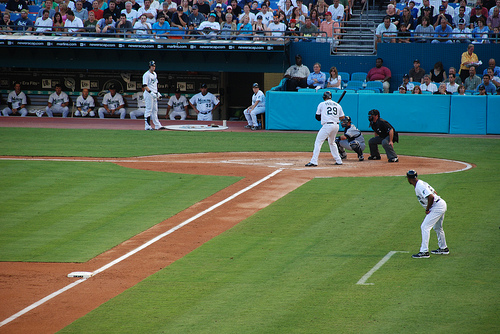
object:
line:
[0, 149, 229, 165]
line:
[358, 279, 376, 285]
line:
[390, 249, 410, 254]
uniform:
[414, 179, 448, 253]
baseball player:
[402, 168, 450, 259]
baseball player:
[140, 59, 167, 131]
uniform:
[141, 70, 166, 131]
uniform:
[242, 89, 265, 127]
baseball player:
[241, 82, 265, 131]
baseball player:
[188, 84, 221, 122]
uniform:
[187, 92, 220, 121]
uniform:
[167, 94, 187, 120]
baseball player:
[164, 85, 190, 120]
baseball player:
[96, 81, 128, 120]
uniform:
[96, 93, 127, 119]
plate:
[276, 161, 296, 166]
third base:
[62, 270, 95, 280]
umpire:
[362, 107, 398, 162]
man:
[458, 42, 479, 83]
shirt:
[458, 51, 481, 70]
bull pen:
[1, 27, 500, 123]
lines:
[352, 252, 399, 286]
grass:
[2, 125, 500, 333]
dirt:
[0, 141, 478, 333]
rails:
[0, 23, 330, 40]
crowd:
[315, 10, 341, 40]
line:
[0, 168, 287, 328]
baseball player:
[303, 89, 345, 169]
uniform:
[309, 100, 344, 166]